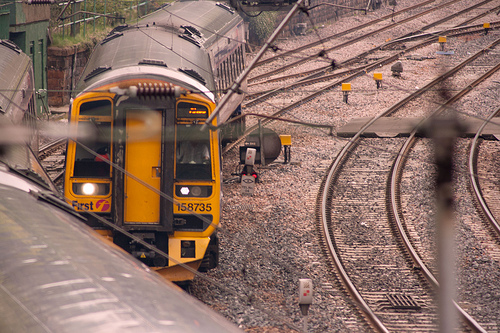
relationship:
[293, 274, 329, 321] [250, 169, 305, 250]
pole on ground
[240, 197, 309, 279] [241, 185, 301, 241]
rocks on floor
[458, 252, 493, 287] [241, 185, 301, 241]
rocks on floor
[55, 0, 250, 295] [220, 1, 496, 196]
train running on track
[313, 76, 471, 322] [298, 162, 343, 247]
railway track made with metal rod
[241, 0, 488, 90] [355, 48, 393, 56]
railway track made with metal rod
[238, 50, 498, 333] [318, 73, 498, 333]
stone beside tracks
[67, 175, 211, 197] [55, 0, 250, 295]
lights on train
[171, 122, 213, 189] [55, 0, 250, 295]
windsheild on train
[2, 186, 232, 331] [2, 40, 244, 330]
top on train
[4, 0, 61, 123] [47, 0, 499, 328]
hut on train way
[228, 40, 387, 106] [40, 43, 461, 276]
cables in station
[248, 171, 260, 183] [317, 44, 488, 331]
indicator light between track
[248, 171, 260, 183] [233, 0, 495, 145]
indicator light between track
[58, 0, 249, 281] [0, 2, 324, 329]
train parked in station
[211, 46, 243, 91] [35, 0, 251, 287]
window of train